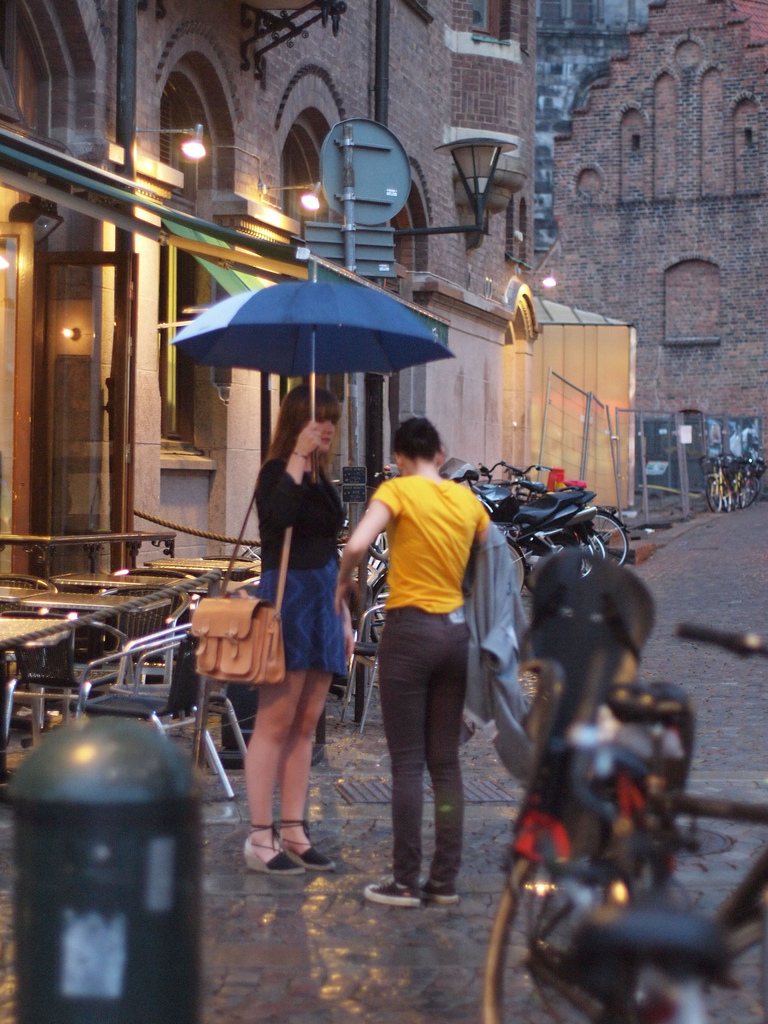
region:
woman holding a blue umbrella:
[168, 259, 456, 873]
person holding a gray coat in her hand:
[333, 419, 531, 909]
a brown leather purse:
[193, 453, 295, 684]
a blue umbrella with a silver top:
[168, 257, 453, 483]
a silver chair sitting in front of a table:
[0, 619, 233, 802]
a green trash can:
[7, 712, 201, 1022]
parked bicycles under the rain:
[460, 461, 623, 579]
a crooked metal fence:
[540, 368, 759, 524]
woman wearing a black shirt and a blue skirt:
[243, 388, 354, 877]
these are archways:
[103, 73, 260, 180]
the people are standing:
[140, 150, 545, 729]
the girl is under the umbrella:
[243, 418, 418, 878]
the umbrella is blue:
[162, 304, 530, 468]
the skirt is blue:
[223, 536, 418, 726]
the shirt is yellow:
[342, 473, 524, 635]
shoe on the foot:
[352, 881, 417, 907]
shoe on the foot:
[261, 832, 289, 873]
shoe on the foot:
[258, 816, 326, 879]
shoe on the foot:
[418, 883, 453, 915]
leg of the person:
[393, 833, 432, 868]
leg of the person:
[444, 807, 484, 853]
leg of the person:
[255, 745, 283, 811]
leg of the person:
[283, 768, 302, 814]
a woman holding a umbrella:
[173, 260, 458, 871]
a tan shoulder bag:
[192, 472, 302, 685]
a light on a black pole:
[398, 125, 517, 238]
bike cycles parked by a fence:
[702, 452, 757, 511]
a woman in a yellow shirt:
[329, 416, 489, 909]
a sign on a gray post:
[302, 116, 412, 272]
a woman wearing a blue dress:
[245, 373, 345, 872]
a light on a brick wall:
[55, 326, 80, 345]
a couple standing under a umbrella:
[187, 256, 508, 905]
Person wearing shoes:
[359, 866, 475, 913]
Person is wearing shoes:
[359, 867, 470, 914]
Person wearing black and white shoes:
[363, 863, 469, 915]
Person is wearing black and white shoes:
[355, 867, 464, 918]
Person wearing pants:
[365, 589, 486, 885]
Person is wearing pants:
[367, 602, 490, 901]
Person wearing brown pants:
[360, 599, 478, 882]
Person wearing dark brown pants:
[364, 599, 490, 886]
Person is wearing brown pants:
[374, 593, 493, 881]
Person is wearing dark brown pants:
[368, 599, 486, 889]